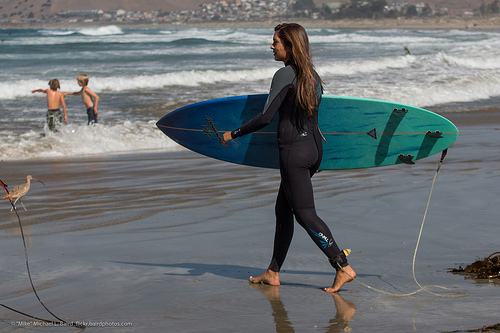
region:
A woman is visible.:
[225, 32, 312, 286]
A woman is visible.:
[295, 107, 390, 328]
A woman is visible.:
[242, 31, 357, 303]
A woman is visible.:
[271, 171, 312, 322]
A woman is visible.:
[261, 84, 329, 329]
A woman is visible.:
[235, 45, 276, 242]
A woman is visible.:
[250, 94, 311, 272]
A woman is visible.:
[320, 134, 358, 328]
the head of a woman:
[265, 20, 310, 65]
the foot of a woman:
[243, 261, 285, 288]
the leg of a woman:
[277, 149, 352, 260]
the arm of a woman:
[233, 65, 290, 139]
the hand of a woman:
[216, 125, 237, 150]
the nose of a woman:
[267, 40, 275, 50]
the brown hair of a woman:
[273, 22, 324, 112]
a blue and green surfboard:
[152, 90, 460, 175]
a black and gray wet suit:
[227, 62, 357, 273]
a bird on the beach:
[0, 170, 49, 223]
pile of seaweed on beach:
[450, 242, 498, 284]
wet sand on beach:
[176, 287, 330, 331]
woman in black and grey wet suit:
[252, 20, 359, 297]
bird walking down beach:
[6, 167, 64, 218]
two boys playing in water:
[41, 68, 121, 150]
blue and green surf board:
[149, 94, 461, 174]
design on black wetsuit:
[301, 222, 346, 254]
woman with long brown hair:
[270, 16, 330, 117]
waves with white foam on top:
[336, 59, 470, 108]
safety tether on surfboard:
[349, 130, 461, 325]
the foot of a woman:
[317, 257, 357, 296]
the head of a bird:
[22, 172, 46, 187]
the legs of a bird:
[8, 192, 31, 213]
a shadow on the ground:
[102, 246, 387, 301]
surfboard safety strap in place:
[318, 143, 453, 301]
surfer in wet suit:
[216, 25, 361, 300]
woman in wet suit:
[221, 22, 358, 291]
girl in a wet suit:
[244, 25, 359, 295]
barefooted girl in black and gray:
[217, 20, 362, 295]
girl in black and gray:
[216, 24, 355, 294]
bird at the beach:
[0, 167, 51, 217]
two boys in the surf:
[23, 70, 115, 141]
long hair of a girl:
[267, 17, 327, 113]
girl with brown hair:
[262, 20, 324, 110]